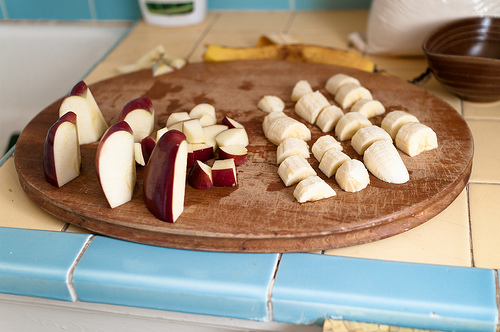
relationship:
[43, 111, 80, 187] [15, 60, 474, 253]
apple on top of board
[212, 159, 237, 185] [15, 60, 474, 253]
apple on top of board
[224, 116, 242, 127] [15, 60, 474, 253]
apple on top of board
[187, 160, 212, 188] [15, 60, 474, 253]
apple on top of board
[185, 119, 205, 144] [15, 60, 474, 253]
apple on top of board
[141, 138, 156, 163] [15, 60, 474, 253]
apple on top of board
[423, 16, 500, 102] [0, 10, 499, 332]
bowl on top of counter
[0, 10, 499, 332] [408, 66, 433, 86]
counter has crack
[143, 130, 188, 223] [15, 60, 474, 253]
apple on top of board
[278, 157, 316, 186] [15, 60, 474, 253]
banana on top of board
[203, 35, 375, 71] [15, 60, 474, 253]
peel next to board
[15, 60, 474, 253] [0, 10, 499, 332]
board on top of counter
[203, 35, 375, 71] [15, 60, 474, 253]
peel near board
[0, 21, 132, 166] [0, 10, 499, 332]
sink near counter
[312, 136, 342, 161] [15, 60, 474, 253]
banana on top of board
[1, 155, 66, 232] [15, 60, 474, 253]
tile below board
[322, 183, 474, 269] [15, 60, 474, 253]
tile below board